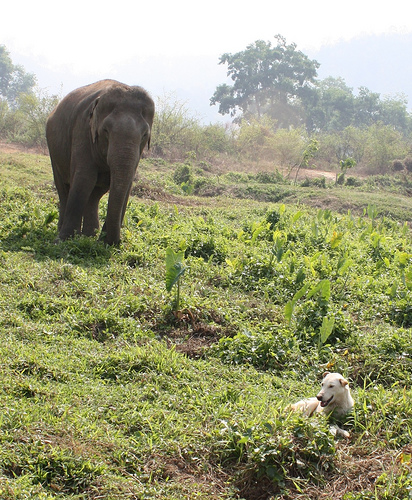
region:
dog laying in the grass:
[287, 367, 359, 436]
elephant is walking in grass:
[27, 72, 171, 268]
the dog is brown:
[279, 364, 371, 438]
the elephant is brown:
[41, 82, 173, 221]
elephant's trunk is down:
[100, 154, 130, 268]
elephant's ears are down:
[80, 86, 178, 168]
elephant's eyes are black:
[96, 120, 150, 144]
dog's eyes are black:
[312, 378, 343, 393]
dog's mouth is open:
[312, 395, 335, 411]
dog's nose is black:
[312, 390, 326, 402]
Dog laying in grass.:
[284, 359, 374, 454]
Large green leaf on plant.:
[154, 241, 204, 326]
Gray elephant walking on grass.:
[49, 63, 159, 261]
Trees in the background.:
[269, 15, 366, 159]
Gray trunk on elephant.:
[98, 104, 162, 257]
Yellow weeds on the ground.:
[389, 447, 407, 482]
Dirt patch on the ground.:
[266, 145, 377, 190]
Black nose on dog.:
[312, 366, 359, 446]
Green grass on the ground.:
[87, 369, 174, 433]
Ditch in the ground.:
[213, 166, 314, 224]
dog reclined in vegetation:
[290, 368, 360, 438]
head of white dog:
[312, 375, 345, 409]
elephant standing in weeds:
[43, 72, 164, 256]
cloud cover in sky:
[260, 12, 375, 47]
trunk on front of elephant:
[98, 139, 149, 253]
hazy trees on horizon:
[332, 34, 408, 84]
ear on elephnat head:
[81, 92, 109, 144]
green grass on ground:
[103, 358, 198, 426]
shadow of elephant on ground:
[17, 222, 107, 266]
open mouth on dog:
[313, 391, 337, 412]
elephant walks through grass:
[61, 88, 165, 267]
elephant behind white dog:
[51, 75, 158, 273]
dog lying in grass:
[293, 371, 365, 449]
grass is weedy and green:
[193, 209, 410, 366]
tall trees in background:
[203, 47, 362, 184]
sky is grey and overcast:
[83, 21, 143, 43]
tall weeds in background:
[184, 121, 291, 173]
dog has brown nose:
[309, 386, 333, 409]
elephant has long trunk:
[99, 131, 131, 248]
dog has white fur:
[281, 372, 332, 405]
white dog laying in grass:
[284, 368, 371, 442]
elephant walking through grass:
[35, 78, 167, 246]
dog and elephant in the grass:
[41, 74, 371, 420]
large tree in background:
[212, 40, 326, 134]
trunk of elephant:
[104, 146, 129, 259]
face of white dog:
[309, 366, 349, 410]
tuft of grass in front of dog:
[218, 414, 336, 489]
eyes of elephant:
[100, 114, 155, 149]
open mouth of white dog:
[314, 391, 335, 408]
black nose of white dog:
[316, 391, 325, 403]